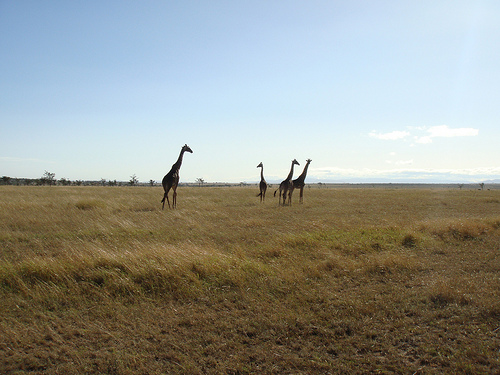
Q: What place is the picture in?
A: It is at the plain.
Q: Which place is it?
A: It is a plain.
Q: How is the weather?
A: It is cloudless.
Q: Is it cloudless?
A: Yes, it is cloudless.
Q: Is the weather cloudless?
A: Yes, it is cloudless.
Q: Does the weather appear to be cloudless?
A: Yes, it is cloudless.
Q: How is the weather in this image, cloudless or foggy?
A: It is cloudless.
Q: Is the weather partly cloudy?
A: No, it is cloudless.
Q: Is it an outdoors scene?
A: Yes, it is outdoors.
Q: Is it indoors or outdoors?
A: It is outdoors.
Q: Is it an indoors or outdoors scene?
A: It is outdoors.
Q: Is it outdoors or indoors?
A: It is outdoors.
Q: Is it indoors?
A: No, it is outdoors.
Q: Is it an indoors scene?
A: No, it is outdoors.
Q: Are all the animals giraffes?
A: Yes, all the animals are giraffes.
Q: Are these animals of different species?
A: No, all the animals are giraffes.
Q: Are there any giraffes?
A: Yes, there is a giraffe.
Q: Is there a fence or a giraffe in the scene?
A: Yes, there is a giraffe.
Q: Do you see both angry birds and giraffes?
A: No, there is a giraffe but no angry birds.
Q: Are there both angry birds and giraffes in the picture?
A: No, there is a giraffe but no angry birds.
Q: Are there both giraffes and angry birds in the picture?
A: No, there is a giraffe but no angry birds.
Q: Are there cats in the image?
A: No, there are no cats.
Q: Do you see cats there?
A: No, there are no cats.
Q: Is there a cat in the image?
A: No, there are no cats.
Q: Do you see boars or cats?
A: No, there are no cats or boars.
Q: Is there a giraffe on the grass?
A: Yes, there is a giraffe on the grass.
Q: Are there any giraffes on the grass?
A: Yes, there is a giraffe on the grass.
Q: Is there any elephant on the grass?
A: No, there is a giraffe on the grass.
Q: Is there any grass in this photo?
A: Yes, there is grass.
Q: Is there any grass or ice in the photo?
A: Yes, there is grass.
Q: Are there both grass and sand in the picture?
A: No, there is grass but no sand.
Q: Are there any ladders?
A: No, there are no ladders.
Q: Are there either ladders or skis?
A: No, there are no ladders or skis.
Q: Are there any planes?
A: No, there are no planes.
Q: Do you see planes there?
A: No, there are no planes.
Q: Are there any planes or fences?
A: No, there are no planes or fences.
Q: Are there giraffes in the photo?
A: Yes, there is a giraffe.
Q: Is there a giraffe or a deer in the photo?
A: Yes, there is a giraffe.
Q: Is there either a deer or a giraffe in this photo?
A: Yes, there is a giraffe.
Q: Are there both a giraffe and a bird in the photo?
A: No, there is a giraffe but no birds.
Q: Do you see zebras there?
A: No, there are no zebras.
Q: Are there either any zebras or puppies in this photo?
A: No, there are no zebras or puppies.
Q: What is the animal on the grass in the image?
A: The animal is a giraffe.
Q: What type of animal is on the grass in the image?
A: The animal is a giraffe.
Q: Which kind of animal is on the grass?
A: The animal is a giraffe.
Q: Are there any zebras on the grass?
A: No, there is a giraffe on the grass.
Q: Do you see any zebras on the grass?
A: No, there is a giraffe on the grass.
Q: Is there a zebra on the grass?
A: No, there is a giraffe on the grass.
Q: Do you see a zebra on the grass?
A: No, there is a giraffe on the grass.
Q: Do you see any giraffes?
A: Yes, there is a giraffe.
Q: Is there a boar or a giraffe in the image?
A: Yes, there is a giraffe.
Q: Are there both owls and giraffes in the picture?
A: No, there is a giraffe but no owls.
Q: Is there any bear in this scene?
A: No, there are no bears.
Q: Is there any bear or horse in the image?
A: No, there are no bears or horses.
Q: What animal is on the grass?
A: The animal is a giraffe.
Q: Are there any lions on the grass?
A: No, there is a giraffe on the grass.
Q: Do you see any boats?
A: No, there are no boats.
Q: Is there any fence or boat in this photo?
A: No, there are no boats or fences.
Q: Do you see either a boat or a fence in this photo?
A: No, there are no boats or fences.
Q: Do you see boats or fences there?
A: No, there are no boats or fences.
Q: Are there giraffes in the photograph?
A: Yes, there is a giraffe.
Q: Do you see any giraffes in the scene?
A: Yes, there is a giraffe.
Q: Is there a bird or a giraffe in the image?
A: Yes, there is a giraffe.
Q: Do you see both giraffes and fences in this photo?
A: No, there is a giraffe but no fences.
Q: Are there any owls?
A: No, there are no owls.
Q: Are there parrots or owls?
A: No, there are no owls or parrots.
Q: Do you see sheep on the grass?
A: No, there is a giraffe on the grass.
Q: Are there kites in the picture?
A: No, there are no kites.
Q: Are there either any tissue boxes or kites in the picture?
A: No, there are no kites or tissue boxes.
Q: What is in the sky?
A: The clouds are in the sky.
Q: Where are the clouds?
A: The clouds are in the sky.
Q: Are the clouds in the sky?
A: Yes, the clouds are in the sky.